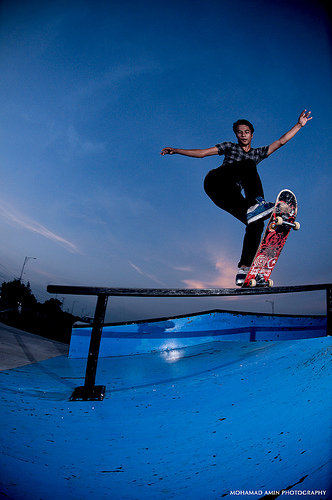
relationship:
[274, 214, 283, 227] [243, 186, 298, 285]
wheel on a skateboard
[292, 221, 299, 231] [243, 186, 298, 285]
wheel on a skateboard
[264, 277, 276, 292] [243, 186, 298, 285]
wheel on a skateboard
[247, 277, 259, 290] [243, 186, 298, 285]
wheel on a skateboard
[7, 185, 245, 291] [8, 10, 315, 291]
clouds in sky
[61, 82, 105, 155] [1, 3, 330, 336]
cloud in sky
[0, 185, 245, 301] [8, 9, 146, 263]
clouds in sky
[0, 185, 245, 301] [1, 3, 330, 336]
clouds in sky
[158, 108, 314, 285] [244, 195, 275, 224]
skateboard under feet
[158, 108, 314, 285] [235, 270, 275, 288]
skateboard under feet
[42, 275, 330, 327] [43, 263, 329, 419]
rail on ramp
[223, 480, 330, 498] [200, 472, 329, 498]
copyright on bottom right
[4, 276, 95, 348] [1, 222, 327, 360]
trees growing in background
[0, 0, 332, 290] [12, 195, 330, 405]
sky above skate park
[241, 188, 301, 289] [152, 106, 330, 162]
skateboard has arms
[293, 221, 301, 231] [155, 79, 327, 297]
wheel of skater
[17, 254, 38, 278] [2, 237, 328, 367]
pole in background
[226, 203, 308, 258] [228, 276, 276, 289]
shoes with sole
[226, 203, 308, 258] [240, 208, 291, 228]
shoes with sole